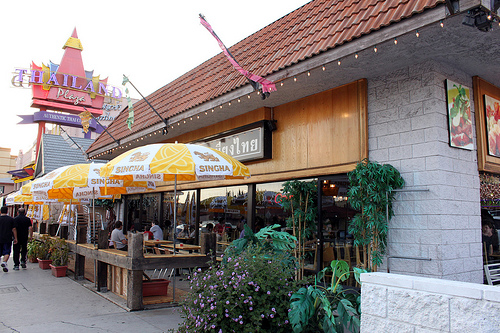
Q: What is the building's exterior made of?
A: Brick.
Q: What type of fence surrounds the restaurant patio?
A: Wooden.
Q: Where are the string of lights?
A: Hanging from building.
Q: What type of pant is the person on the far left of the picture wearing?
A: Shorts.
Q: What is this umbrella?
A: Yellow.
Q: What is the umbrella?
A: Yellow.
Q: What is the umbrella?
A: Yellow.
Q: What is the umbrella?
A: Yellow.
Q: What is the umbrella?
A: Yellow.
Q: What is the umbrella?
A: Yellow.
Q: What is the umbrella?
A: Yellow.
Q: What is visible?
A: The brick wall.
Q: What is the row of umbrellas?
A: Orange and white.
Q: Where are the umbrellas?
A: Above the tables.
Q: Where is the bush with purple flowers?
A: On the sidewalk.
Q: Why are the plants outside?
A: To grow in the sun.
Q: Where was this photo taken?
A: Outside near a restaurant.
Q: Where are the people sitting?
A: Outside at a patio table.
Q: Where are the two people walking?
A: On the sidewalk.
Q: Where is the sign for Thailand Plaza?
A: At the top left.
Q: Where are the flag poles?
A: Attached to the roof.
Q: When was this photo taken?
A: During the daytime.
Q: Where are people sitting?
A: Under umbrellas.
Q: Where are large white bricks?
A: On the building.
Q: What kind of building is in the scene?
A: A restaurant.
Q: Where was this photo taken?
A: Outside of a restaurant.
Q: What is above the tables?
A: Umbrellas.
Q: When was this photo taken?
A: During the daytime.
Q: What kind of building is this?
A: Restaurant.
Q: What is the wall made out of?
A: Blocks.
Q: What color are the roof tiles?
A: Red.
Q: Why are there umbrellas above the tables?
A: To shade diners.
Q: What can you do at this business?
A: Order food.